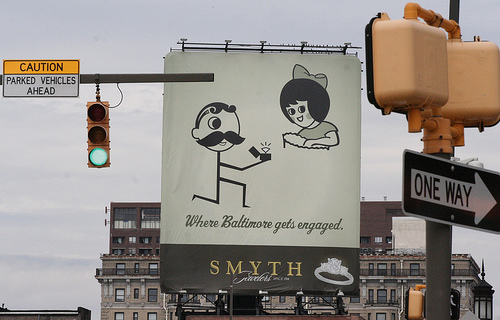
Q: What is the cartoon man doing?
A: Kneeling.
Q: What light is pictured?
A: Traffic.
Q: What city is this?
A: Baltimore.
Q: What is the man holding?
A: Ring.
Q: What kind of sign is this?
A: Advertisement.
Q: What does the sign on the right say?
A: One way.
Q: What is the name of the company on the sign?
A: Smyth.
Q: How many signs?
A: 3.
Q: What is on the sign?
A: Writing.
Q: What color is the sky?
A: Blue.